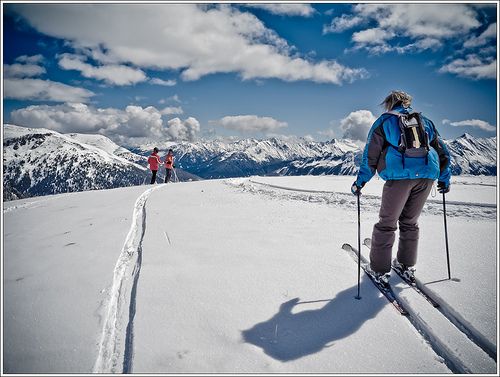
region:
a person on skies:
[265, 8, 495, 273]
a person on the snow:
[280, 46, 492, 358]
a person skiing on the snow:
[322, 37, 467, 372]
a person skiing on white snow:
[319, 43, 497, 365]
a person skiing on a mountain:
[50, 16, 496, 376]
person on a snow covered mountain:
[84, 45, 461, 371]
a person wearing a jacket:
[309, 34, 482, 255]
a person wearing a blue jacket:
[326, 57, 465, 226]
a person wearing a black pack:
[297, 41, 498, 237]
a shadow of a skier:
[217, 64, 474, 373]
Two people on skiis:
[138, 143, 186, 193]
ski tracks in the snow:
[109, 174, 162, 364]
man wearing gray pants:
[379, 170, 429, 287]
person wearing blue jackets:
[361, 112, 450, 182]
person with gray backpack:
[387, 110, 436, 174]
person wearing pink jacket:
[143, 153, 167, 173]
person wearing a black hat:
[152, 143, 162, 155]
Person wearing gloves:
[348, 177, 363, 195]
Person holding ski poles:
[354, 113, 457, 201]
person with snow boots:
[351, 246, 423, 303]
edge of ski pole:
[344, 284, 394, 313]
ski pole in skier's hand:
[335, 177, 370, 293]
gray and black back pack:
[381, 109, 441, 179]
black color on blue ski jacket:
[362, 123, 412, 169]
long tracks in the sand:
[89, 215, 150, 331]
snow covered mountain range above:
[216, 135, 309, 170]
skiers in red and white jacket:
[134, 137, 192, 196]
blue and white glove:
[344, 175, 368, 196]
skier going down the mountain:
[324, 72, 477, 267]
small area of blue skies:
[192, 92, 309, 110]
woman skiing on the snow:
[329, 89, 483, 306]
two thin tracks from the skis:
[412, 288, 499, 376]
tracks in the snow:
[93, 178, 182, 375]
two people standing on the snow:
[140, 138, 185, 189]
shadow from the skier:
[232, 266, 464, 374]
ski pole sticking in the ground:
[349, 196, 372, 304]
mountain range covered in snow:
[4, 119, 492, 195]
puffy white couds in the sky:
[4, 6, 499, 138]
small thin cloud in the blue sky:
[151, 74, 179, 89]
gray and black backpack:
[383, 106, 439, 167]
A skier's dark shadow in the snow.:
[243, 272, 402, 360]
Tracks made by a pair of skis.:
[92, 186, 164, 374]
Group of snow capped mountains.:
[199, 137, 324, 154]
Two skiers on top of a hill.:
[149, 145, 177, 180]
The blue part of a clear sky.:
[209, 86, 381, 111]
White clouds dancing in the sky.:
[116, 6, 496, 79]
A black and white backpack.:
[399, 115, 434, 160]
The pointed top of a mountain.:
[29, 123, 66, 145]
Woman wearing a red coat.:
[145, 146, 162, 176]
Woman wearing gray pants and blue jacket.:
[355, 88, 444, 275]